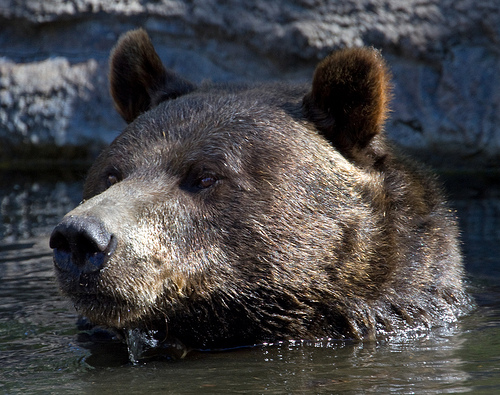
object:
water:
[1, 161, 500, 395]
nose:
[49, 218, 110, 254]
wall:
[0, 0, 497, 161]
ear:
[110, 28, 385, 157]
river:
[1, 159, 499, 394]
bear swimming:
[20, 19, 497, 372]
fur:
[83, 226, 465, 343]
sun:
[118, 179, 186, 274]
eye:
[179, 170, 218, 192]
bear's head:
[50, 25, 475, 362]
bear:
[50, 27, 478, 352]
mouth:
[63, 285, 182, 323]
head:
[48, 29, 390, 328]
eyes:
[100, 169, 119, 184]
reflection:
[296, 336, 470, 395]